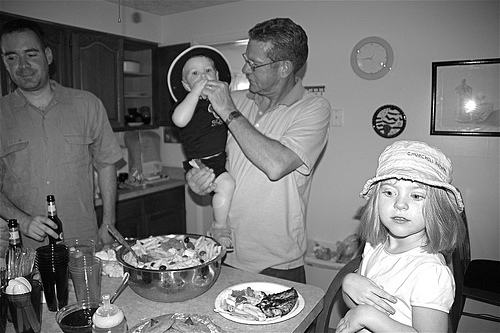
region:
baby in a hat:
[162, 39, 245, 251]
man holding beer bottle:
[1, 27, 116, 253]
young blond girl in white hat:
[342, 139, 470, 331]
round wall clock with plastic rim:
[345, 32, 397, 84]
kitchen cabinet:
[71, 27, 171, 138]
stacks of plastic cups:
[34, 243, 104, 313]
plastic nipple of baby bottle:
[89, 292, 124, 332]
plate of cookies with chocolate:
[130, 309, 217, 331]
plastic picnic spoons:
[0, 275, 45, 331]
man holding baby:
[160, 18, 335, 270]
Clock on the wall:
[348, 36, 393, 77]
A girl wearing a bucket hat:
[350, 135, 465, 327]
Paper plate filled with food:
[212, 275, 298, 320]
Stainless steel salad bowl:
[115, 230, 225, 300]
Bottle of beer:
[35, 190, 62, 240]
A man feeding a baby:
[166, 15, 326, 175]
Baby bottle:
[90, 291, 123, 331]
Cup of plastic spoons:
[1, 273, 46, 329]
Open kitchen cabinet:
[116, 32, 172, 124]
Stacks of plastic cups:
[33, 242, 105, 301]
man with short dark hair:
[2, 21, 129, 294]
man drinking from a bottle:
[0, 181, 141, 314]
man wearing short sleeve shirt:
[0, 67, 129, 261]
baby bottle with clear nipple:
[72, 293, 156, 330]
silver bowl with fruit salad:
[82, 225, 257, 305]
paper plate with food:
[197, 273, 309, 326]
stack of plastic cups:
[52, 236, 133, 322]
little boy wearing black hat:
[160, 34, 255, 251]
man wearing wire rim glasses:
[194, 21, 339, 183]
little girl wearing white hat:
[320, 138, 469, 325]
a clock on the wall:
[327, 14, 405, 104]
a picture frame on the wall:
[399, 36, 496, 151]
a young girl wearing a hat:
[343, 133, 495, 331]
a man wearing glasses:
[234, 19, 310, 111]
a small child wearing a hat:
[154, 15, 262, 203]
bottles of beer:
[3, 195, 95, 277]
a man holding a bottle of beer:
[0, 1, 134, 248]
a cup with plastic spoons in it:
[4, 270, 54, 326]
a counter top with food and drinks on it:
[3, 188, 340, 329]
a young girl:
[343, 120, 491, 317]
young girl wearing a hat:
[332, 133, 459, 330]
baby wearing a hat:
[158, 41, 242, 233]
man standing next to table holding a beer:
[2, 30, 126, 265]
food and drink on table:
[2, 213, 285, 330]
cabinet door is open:
[112, 31, 192, 133]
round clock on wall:
[348, 36, 395, 81]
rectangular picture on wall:
[422, 55, 497, 131]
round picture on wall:
[366, 101, 406, 138]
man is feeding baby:
[156, 19, 320, 154]